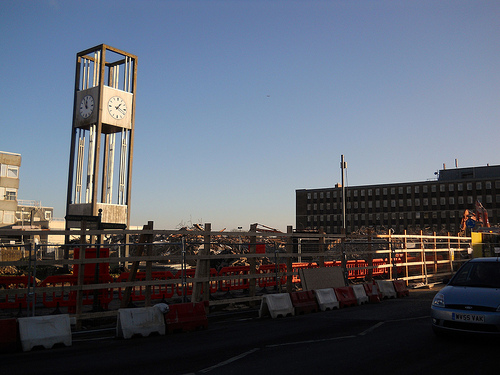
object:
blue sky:
[0, 0, 500, 232]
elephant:
[327, 37, 470, 130]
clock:
[107, 96, 127, 121]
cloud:
[0, 0, 65, 145]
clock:
[79, 94, 95, 118]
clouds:
[258, 0, 500, 187]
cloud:
[27, 188, 296, 232]